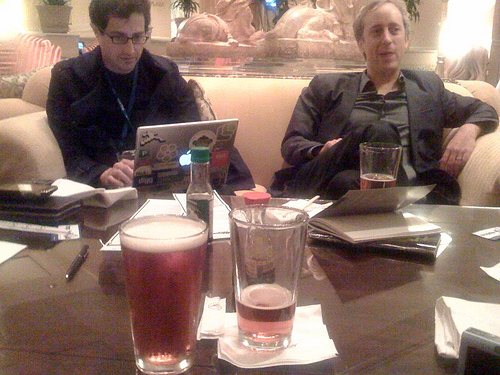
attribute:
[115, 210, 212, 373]
full glass — beer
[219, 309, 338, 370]
napkin — on table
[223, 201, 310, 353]
glass — nearly empty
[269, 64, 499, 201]
clothes — dark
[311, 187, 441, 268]
books — on table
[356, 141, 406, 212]
glass — on table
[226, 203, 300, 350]
glass — tall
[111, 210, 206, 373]
glass — tall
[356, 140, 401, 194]
glass — tall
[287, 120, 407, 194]
legs — crossed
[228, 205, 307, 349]
glass — sitting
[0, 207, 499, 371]
table — brown, shiny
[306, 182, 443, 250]
notebooks — stacked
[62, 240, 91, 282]
pen — on table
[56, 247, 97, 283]
pen — black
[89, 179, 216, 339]
glass — full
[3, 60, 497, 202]
couch — beige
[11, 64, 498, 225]
couch — beige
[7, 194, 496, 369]
table — large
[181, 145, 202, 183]
apple icon — glowing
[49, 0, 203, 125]
man — wearing, looking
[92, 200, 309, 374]
glasses — tall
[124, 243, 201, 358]
beverage — pink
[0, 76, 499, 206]
sofa — tan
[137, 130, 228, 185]
stickers — on cover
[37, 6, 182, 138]
man — working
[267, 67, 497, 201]
jacket — black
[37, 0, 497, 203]
men — sitting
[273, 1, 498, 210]
man — looking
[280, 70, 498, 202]
shirt — black, collared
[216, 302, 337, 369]
napkin — white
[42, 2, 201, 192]
man — seated, looking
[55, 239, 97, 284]
pen — ink, black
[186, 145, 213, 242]
condiment bottle — behind, covered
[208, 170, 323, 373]
glass — empty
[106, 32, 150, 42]
eyeglasses — black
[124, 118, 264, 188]
laptop — covered in stickers